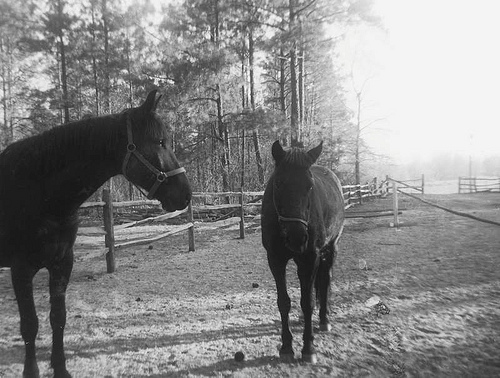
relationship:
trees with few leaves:
[193, 15, 313, 258] [170, 10, 215, 66]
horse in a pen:
[261, 139, 347, 366] [345, 172, 499, 377]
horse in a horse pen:
[1, 89, 193, 377] [345, 172, 499, 377]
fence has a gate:
[194, 188, 260, 242] [419, 171, 463, 197]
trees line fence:
[0, 0, 392, 198] [76, 174, 425, 272]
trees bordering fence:
[0, 0, 392, 198] [76, 174, 425, 272]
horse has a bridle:
[1, 89, 193, 377] [121, 109, 188, 201]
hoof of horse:
[302, 349, 318, 364] [261, 139, 347, 366]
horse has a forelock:
[1, 89, 193, 377] [283, 148, 316, 167]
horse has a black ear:
[1, 89, 193, 377] [140, 87, 161, 113]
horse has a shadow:
[261, 139, 347, 366] [68, 320, 281, 361]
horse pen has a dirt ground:
[345, 172, 499, 377] [72, 271, 272, 377]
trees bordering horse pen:
[0, 0, 392, 198] [345, 172, 499, 377]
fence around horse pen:
[76, 174, 425, 272] [345, 172, 499, 377]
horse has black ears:
[261, 139, 347, 366] [306, 138, 323, 170]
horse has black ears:
[1, 89, 193, 377] [140, 87, 161, 113]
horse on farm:
[261, 139, 347, 366] [345, 172, 499, 377]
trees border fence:
[0, 0, 392, 198] [194, 188, 260, 242]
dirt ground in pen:
[72, 271, 272, 377] [345, 172, 499, 377]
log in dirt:
[414, 189, 499, 228] [336, 237, 499, 377]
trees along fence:
[0, 0, 392, 198] [76, 174, 425, 272]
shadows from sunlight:
[68, 320, 281, 361] [72, 271, 272, 377]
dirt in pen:
[336, 237, 499, 377] [345, 172, 499, 377]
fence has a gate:
[76, 174, 425, 272] [419, 171, 463, 197]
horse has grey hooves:
[261, 139, 347, 366] [302, 349, 318, 364]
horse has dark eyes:
[1, 89, 193, 377] [158, 137, 164, 148]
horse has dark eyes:
[261, 139, 347, 366] [307, 179, 315, 192]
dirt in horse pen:
[336, 237, 499, 377] [345, 172, 499, 377]